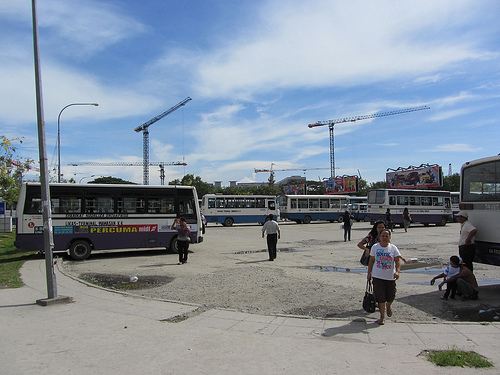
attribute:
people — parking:
[167, 211, 437, 304]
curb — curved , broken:
[102, 272, 344, 335]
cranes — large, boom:
[138, 79, 400, 194]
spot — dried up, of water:
[85, 265, 160, 294]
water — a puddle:
[395, 254, 440, 282]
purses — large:
[347, 245, 378, 318]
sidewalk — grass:
[255, 323, 365, 365]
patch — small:
[401, 337, 481, 370]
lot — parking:
[203, 257, 291, 301]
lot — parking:
[190, 276, 247, 296]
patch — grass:
[421, 334, 481, 372]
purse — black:
[359, 294, 372, 314]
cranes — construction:
[110, 93, 358, 177]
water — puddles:
[98, 259, 418, 288]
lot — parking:
[166, 257, 261, 304]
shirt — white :
[263, 219, 279, 233]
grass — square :
[422, 346, 492, 367]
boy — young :
[447, 263, 478, 298]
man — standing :
[453, 210, 479, 281]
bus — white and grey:
[18, 179, 204, 254]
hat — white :
[455, 209, 470, 218]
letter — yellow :
[88, 225, 106, 237]